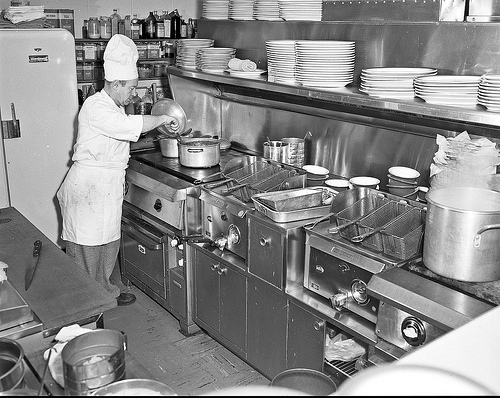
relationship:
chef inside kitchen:
[55, 33, 181, 305] [1, 0, 498, 398]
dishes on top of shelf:
[296, 39, 356, 89] [166, 62, 498, 137]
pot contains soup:
[176, 136, 221, 168] [180, 140, 219, 144]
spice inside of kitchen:
[87, 15, 100, 40] [1, 0, 498, 398]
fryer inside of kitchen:
[303, 188, 425, 327] [1, 0, 498, 398]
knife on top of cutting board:
[24, 239, 44, 291] [0, 206, 118, 330]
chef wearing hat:
[55, 33, 181, 305] [102, 33, 139, 80]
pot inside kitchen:
[176, 136, 221, 168] [1, 0, 498, 398]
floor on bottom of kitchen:
[94, 285, 273, 391] [1, 0, 498, 398]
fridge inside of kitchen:
[0, 27, 76, 249] [1, 0, 498, 398]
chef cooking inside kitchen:
[55, 33, 181, 305] [1, 0, 498, 398]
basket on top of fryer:
[303, 187, 424, 260] [303, 188, 425, 327]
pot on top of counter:
[424, 185, 499, 283] [409, 258, 498, 305]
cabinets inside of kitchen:
[189, 243, 326, 381] [1, 0, 498, 398]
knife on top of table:
[24, 239, 44, 291] [0, 206, 118, 330]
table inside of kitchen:
[0, 203, 106, 354] [1, 0, 498, 398]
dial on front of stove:
[154, 199, 162, 213] [117, 141, 261, 336]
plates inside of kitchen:
[296, 39, 356, 89] [1, 0, 498, 398]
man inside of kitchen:
[62, 32, 137, 290] [1, 0, 498, 398]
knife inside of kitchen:
[24, 239, 44, 291] [1, 0, 498, 398]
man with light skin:
[55, 33, 181, 305] [104, 76, 139, 107]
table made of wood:
[0, 203, 106, 354] [0, 206, 118, 330]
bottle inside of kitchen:
[146, 10, 157, 37] [1, 0, 498, 398]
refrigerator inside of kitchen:
[0, 27, 76, 249] [1, 0, 498, 398]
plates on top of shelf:
[358, 67, 437, 98] [166, 62, 498, 137]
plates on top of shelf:
[414, 77, 479, 108] [166, 62, 498, 137]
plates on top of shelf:
[196, 47, 233, 74] [166, 62, 498, 137]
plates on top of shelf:
[177, 39, 214, 69] [166, 62, 498, 137]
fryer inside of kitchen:
[198, 157, 307, 263] [1, 0, 498, 398]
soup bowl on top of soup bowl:
[388, 165, 419, 182] [387, 175, 417, 188]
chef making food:
[55, 33, 181, 305] [176, 136, 221, 168]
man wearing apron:
[55, 33, 181, 305] [55, 162, 126, 246]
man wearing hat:
[55, 33, 181, 305] [102, 33, 139, 80]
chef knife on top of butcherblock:
[24, 239, 44, 291] [0, 206, 118, 330]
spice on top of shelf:
[87, 15, 100, 40] [75, 38, 197, 42]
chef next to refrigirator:
[55, 33, 181, 305] [0, 27, 76, 249]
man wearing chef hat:
[55, 33, 181, 305] [102, 33, 139, 80]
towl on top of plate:
[229, 58, 256, 72] [226, 68, 267, 78]